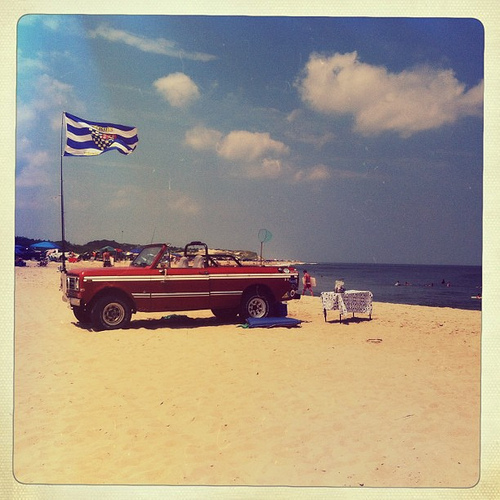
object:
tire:
[242, 296, 269, 323]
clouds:
[151, 71, 202, 111]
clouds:
[296, 59, 484, 137]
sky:
[18, 14, 482, 268]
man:
[302, 270, 314, 297]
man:
[103, 248, 111, 268]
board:
[301, 276, 316, 287]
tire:
[91, 294, 132, 330]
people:
[446, 282, 451, 288]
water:
[406, 288, 470, 307]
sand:
[13, 329, 479, 488]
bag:
[334, 279, 345, 293]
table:
[321, 289, 374, 324]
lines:
[83, 273, 299, 282]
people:
[476, 293, 481, 300]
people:
[404, 281, 409, 286]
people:
[394, 281, 400, 287]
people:
[440, 278, 445, 284]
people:
[429, 282, 434, 287]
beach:
[14, 334, 481, 488]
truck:
[66, 241, 299, 332]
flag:
[62, 111, 139, 157]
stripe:
[65, 131, 90, 155]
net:
[258, 228, 273, 242]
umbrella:
[30, 241, 61, 266]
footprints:
[56, 394, 131, 440]